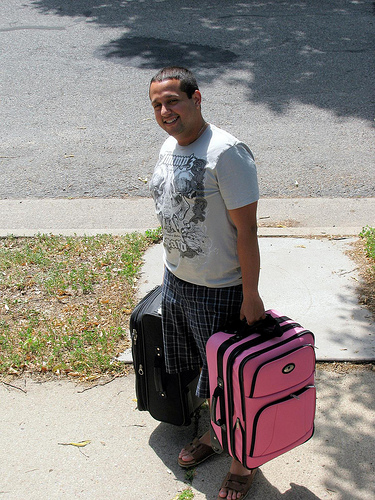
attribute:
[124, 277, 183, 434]
suitcase — black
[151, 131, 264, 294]
shirt — grey, graphic, tee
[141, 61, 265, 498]
guy — smiling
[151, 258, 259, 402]
shorts — black, plaid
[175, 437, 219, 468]
sandal — leather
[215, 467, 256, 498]
sandal — leather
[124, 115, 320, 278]
t-shirt — grey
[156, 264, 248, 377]
plaid shorts — blue, white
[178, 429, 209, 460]
feet — bare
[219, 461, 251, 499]
feet — bare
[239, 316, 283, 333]
handle — black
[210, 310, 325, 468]
suitcase — black, pink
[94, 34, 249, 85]
patch — black, asphalt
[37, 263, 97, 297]
grass — green, brown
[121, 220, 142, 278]
grass — green, brown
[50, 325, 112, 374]
grass — green, brown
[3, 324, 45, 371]
grass — green, brown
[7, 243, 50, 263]
grass — green, brown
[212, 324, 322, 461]
suitcase — pink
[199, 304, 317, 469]
suitcase — pink, black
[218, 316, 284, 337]
handle — black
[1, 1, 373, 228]
road — gray